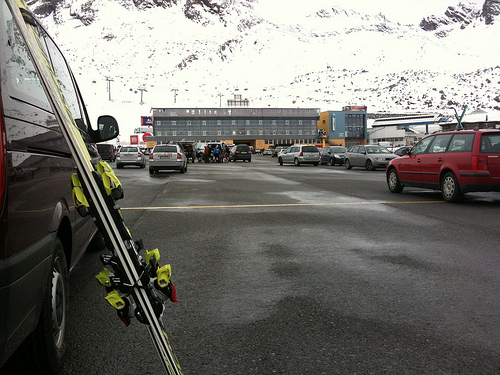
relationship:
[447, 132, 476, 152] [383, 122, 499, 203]
window of car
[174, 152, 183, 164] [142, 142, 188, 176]
taillight of car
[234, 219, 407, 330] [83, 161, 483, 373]
section of pavement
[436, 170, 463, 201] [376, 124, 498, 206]
tire of car